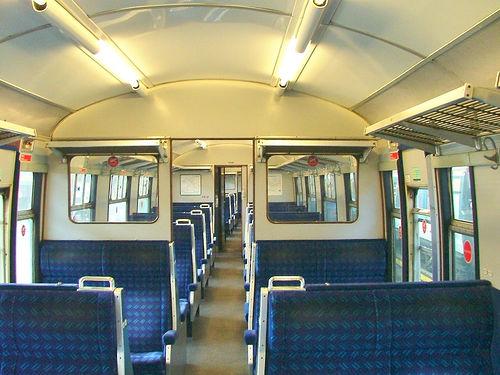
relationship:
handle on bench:
[268, 275, 306, 292] [261, 280, 498, 374]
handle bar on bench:
[76, 276, 115, 291] [1, 287, 126, 374]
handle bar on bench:
[174, 217, 191, 225] [171, 220, 198, 339]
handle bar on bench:
[189, 208, 203, 215] [173, 214, 207, 297]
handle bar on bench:
[199, 202, 209, 208] [171, 201, 214, 253]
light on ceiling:
[276, 38, 308, 86] [164, 30, 267, 123]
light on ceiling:
[84, 28, 145, 89] [164, 30, 267, 123]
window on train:
[61, 146, 166, 228] [14, 6, 472, 358]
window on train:
[411, 188, 442, 282] [14, 6, 472, 358]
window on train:
[388, 215, 407, 282] [14, 6, 472, 358]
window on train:
[17, 170, 29, 210] [14, 6, 472, 358]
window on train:
[61, 146, 166, 228] [27, 36, 467, 373]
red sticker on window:
[459, 236, 478, 266] [438, 161, 487, 287]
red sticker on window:
[462, 240, 472, 264] [441, 164, 473, 275]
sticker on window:
[14, 135, 46, 187] [378, 162, 485, 301]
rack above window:
[364, 84, 500, 154] [437, 156, 482, 286]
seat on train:
[246, 238, 391, 334] [14, 6, 472, 358]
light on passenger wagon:
[95, 41, 141, 89] [0, 0, 499, 372]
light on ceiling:
[276, 38, 308, 86] [0, 0, 499, 142]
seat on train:
[244, 234, 388, 286] [39, 67, 383, 374]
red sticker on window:
[462, 240, 472, 264] [381, 163, 477, 289]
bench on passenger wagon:
[261, 273, 498, 373] [0, 0, 499, 372]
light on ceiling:
[276, 47, 306, 89] [0, 0, 499, 142]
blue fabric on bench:
[0, 282, 120, 374] [31, 238, 176, 372]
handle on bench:
[268, 275, 306, 292] [253, 272, 497, 374]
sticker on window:
[308, 155, 316, 168] [263, 152, 360, 223]